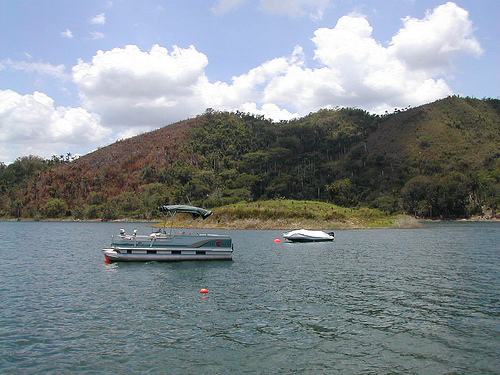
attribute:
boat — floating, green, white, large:
[63, 167, 255, 292]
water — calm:
[255, 274, 399, 345]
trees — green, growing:
[164, 116, 354, 214]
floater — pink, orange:
[188, 278, 224, 305]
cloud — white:
[107, 45, 193, 105]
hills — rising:
[20, 98, 283, 203]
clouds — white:
[67, 40, 257, 132]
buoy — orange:
[6, 112, 221, 217]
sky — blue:
[199, 6, 240, 43]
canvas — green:
[159, 198, 211, 235]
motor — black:
[326, 226, 343, 244]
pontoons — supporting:
[99, 181, 345, 300]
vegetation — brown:
[104, 113, 190, 177]